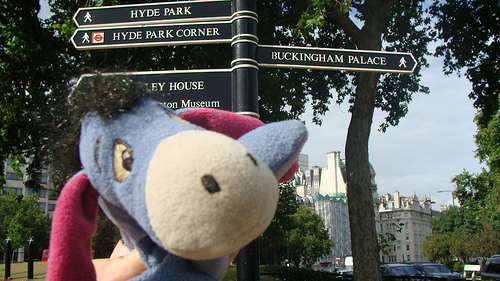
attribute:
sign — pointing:
[268, 38, 435, 85]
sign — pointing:
[74, 6, 236, 21]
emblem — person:
[396, 53, 412, 74]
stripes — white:
[228, 7, 258, 118]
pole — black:
[231, 0, 260, 279]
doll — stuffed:
[76, 84, 317, 279]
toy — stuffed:
[45, 66, 313, 266]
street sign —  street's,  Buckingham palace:
[261, 43, 418, 73]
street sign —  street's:
[72, 0, 233, 27]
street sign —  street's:
[68, 20, 230, 46]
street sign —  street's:
[66, 65, 233, 113]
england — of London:
[21, 8, 498, 268]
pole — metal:
[232, 8, 262, 279]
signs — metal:
[67, 11, 457, 108]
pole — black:
[226, 0, 266, 118]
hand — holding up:
[87, 225, 248, 279]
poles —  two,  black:
[3, 218, 44, 269]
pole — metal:
[213, 7, 285, 127]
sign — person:
[62, 3, 242, 18]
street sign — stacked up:
[72, 2, 417, 276]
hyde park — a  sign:
[104, 2, 209, 22]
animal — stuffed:
[34, 99, 317, 274]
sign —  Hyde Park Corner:
[71, 24, 250, 50]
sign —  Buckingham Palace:
[254, 29, 424, 82]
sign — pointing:
[71, 9, 237, 39]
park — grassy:
[298, 250, 497, 277]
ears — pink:
[177, 108, 296, 180]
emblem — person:
[76, 26, 105, 50]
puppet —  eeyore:
[45, 68, 307, 276]